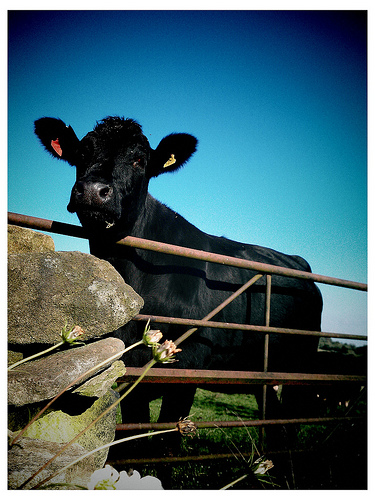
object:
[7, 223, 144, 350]
boulders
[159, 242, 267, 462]
gate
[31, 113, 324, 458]
cow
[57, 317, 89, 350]
flowers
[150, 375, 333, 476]
pasture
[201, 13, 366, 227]
sky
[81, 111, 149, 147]
fur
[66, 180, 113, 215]
nose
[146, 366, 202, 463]
legs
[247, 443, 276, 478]
flower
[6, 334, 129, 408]
rocks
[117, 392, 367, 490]
field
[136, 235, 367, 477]
fence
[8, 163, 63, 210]
fly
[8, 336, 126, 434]
rock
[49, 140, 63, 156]
red tag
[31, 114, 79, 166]
cow's ear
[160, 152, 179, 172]
tag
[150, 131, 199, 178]
ear